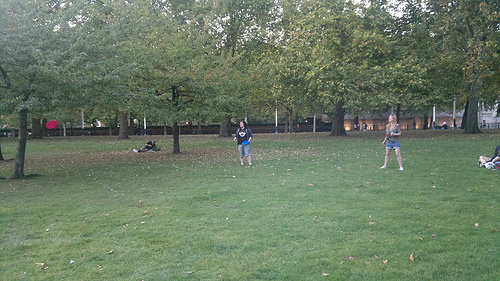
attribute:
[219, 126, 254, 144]
jacket — dark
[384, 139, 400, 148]
jeans — blue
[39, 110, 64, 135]
frisbee — red 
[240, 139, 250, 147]
frisbee — blue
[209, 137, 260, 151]
shorts — dark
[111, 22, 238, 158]
tree — green 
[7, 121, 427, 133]
fence — long, brown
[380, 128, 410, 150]
shorts — denim 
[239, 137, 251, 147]
frisbee — blue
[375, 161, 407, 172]
shoes — white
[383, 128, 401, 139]
shirt — brown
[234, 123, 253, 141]
top — black, white